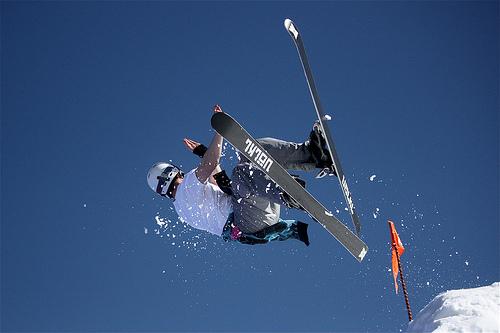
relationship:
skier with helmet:
[128, 18, 376, 265] [139, 160, 184, 198]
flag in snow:
[387, 222, 413, 329] [386, 282, 495, 331]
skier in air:
[128, 18, 376, 265] [1, 3, 493, 264]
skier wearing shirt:
[128, 18, 376, 265] [170, 169, 237, 241]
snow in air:
[367, 170, 478, 288] [1, 3, 493, 264]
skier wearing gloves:
[128, 18, 376, 265] [188, 144, 213, 160]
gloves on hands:
[188, 144, 213, 160] [182, 104, 225, 153]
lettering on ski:
[243, 136, 274, 173] [282, 12, 365, 236]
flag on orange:
[387, 222, 413, 329] [383, 218, 405, 294]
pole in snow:
[392, 246, 413, 320] [386, 282, 495, 331]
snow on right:
[386, 282, 495, 331] [460, 4, 499, 331]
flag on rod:
[387, 222, 413, 329] [388, 223, 416, 322]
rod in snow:
[388, 223, 416, 322] [386, 282, 495, 331]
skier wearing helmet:
[128, 18, 376, 265] [139, 160, 184, 198]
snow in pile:
[386, 282, 495, 331] [401, 278, 498, 332]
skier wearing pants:
[128, 18, 376, 265] [228, 135, 310, 234]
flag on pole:
[387, 222, 413, 329] [392, 246, 413, 320]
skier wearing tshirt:
[128, 18, 376, 265] [170, 169, 237, 241]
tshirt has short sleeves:
[170, 169, 237, 241] [185, 167, 210, 199]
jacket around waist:
[221, 215, 311, 249] [216, 174, 246, 243]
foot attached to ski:
[304, 114, 333, 190] [282, 12, 365, 236]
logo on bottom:
[242, 137, 273, 172] [210, 18, 372, 262]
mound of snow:
[401, 278, 498, 332] [386, 282, 495, 331]